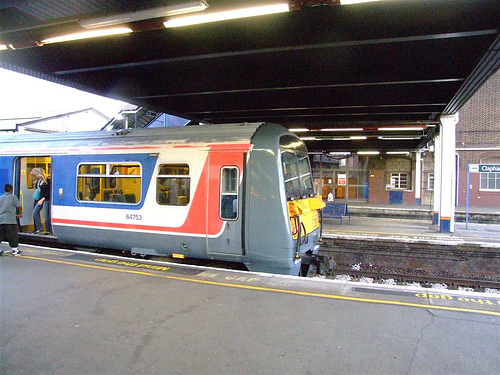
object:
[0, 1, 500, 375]
station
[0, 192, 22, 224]
shirt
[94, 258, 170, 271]
lettering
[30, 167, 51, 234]
woman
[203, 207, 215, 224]
red paint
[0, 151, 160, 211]
blue paint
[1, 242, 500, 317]
stripe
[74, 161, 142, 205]
window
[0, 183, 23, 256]
boy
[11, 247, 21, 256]
white sneakers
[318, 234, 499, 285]
train tracks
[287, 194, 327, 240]
bumper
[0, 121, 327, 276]
train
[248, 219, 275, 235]
grey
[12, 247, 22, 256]
sneaker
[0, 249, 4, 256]
sneaker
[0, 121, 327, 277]
paint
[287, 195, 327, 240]
paint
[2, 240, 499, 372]
platform